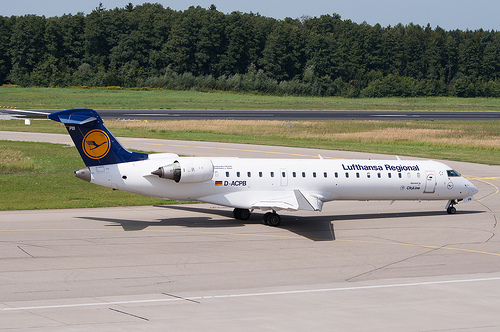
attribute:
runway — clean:
[2, 210, 495, 291]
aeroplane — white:
[46, 103, 483, 224]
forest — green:
[121, 6, 212, 85]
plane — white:
[44, 102, 484, 241]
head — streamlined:
[416, 151, 480, 224]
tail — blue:
[43, 107, 149, 168]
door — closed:
[423, 166, 439, 199]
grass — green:
[120, 87, 168, 113]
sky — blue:
[346, 3, 498, 26]